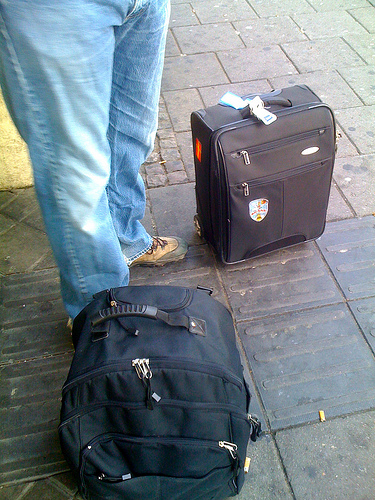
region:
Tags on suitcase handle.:
[218, 89, 277, 121]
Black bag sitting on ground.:
[76, 414, 262, 468]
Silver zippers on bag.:
[132, 358, 151, 373]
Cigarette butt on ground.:
[314, 404, 325, 415]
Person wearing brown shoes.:
[149, 230, 202, 272]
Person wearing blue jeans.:
[59, 223, 108, 281]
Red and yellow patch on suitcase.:
[190, 137, 211, 167]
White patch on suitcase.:
[246, 197, 276, 223]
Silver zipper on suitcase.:
[237, 146, 255, 167]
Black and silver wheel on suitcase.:
[182, 210, 216, 243]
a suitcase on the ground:
[140, 43, 356, 296]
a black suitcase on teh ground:
[176, 96, 355, 232]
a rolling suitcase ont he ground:
[179, 54, 368, 269]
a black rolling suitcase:
[189, 89, 365, 263]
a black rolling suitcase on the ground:
[191, 59, 374, 302]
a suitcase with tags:
[199, 68, 365, 319]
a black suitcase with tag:
[198, 83, 361, 236]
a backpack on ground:
[45, 227, 228, 471]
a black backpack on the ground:
[73, 285, 244, 483]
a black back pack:
[30, 258, 255, 498]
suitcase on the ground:
[159, 58, 369, 258]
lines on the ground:
[263, 295, 368, 443]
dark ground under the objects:
[245, 299, 362, 401]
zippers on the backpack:
[111, 347, 169, 393]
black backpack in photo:
[34, 319, 281, 497]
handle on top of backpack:
[66, 284, 202, 352]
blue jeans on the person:
[15, 10, 217, 243]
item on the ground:
[301, 399, 339, 437]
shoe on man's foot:
[111, 219, 203, 281]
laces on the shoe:
[137, 224, 176, 256]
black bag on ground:
[154, 101, 331, 262]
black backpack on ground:
[82, 306, 247, 496]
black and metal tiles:
[223, 283, 352, 412]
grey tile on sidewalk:
[186, 36, 355, 90]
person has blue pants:
[18, 28, 182, 301]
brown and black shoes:
[121, 231, 185, 261]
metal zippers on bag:
[97, 331, 167, 386]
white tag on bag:
[226, 93, 281, 127]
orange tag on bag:
[189, 138, 208, 166]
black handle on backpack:
[90, 278, 174, 338]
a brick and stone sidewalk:
[6, 42, 366, 496]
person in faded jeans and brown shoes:
[1, 0, 188, 330]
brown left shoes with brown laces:
[132, 236, 188, 267]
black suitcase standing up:
[196, 82, 336, 263]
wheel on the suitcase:
[193, 217, 204, 236]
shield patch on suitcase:
[250, 195, 269, 222]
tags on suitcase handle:
[220, 93, 275, 126]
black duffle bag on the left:
[66, 286, 252, 491]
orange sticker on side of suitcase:
[195, 137, 201, 163]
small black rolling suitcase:
[190, 82, 336, 262]